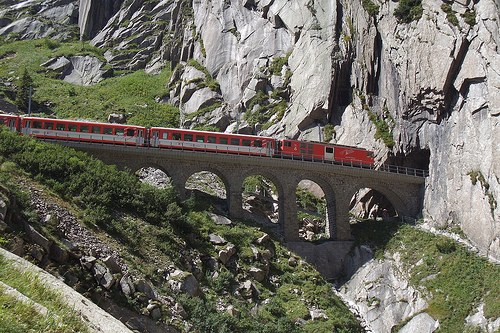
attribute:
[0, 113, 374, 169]
train — red, white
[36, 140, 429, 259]
bridge — stone, grey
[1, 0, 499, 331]
grass — green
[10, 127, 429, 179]
railing — silver, steel, metal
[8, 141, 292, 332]
bushes — green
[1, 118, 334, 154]
windows — black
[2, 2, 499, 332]
rocks — grey, gray, large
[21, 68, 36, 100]
tree — pine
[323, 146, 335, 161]
door — white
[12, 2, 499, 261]
mountain — rocky